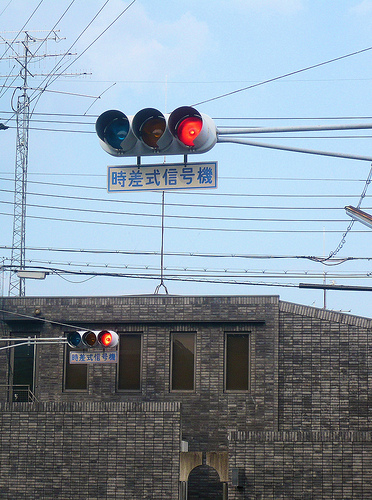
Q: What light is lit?
A: Red.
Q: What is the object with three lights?
A: A stoplight.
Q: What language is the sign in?
A: Chinese.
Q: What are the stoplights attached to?
A: A pole.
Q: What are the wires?
A: Power lines.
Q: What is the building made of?
A: Brick.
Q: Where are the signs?
A: Under the stoplights.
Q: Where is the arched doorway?
A: Under the windows on the right.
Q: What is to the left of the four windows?
A: A door.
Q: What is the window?
A: Tinted.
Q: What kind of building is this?
A: Brick building.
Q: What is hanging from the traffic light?
A: A sign.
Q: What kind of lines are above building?
A: Power lines.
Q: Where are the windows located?
A: Second floor.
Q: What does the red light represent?
A: Cars to stop.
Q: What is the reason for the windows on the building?
A: To look outside.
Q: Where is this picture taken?
A: Asia.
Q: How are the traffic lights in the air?
A: Hanging from posts.